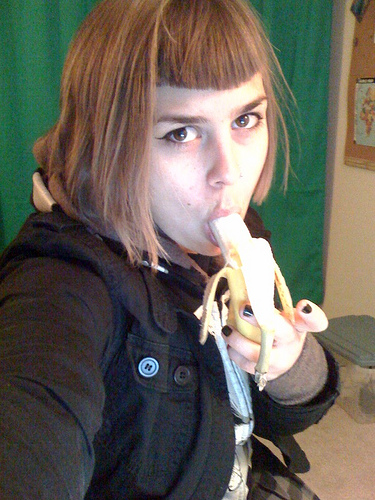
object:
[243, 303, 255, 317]
fingernails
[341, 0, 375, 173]
corkboard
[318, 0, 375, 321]
wall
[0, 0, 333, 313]
curtain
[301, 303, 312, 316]
nails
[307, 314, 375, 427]
plastic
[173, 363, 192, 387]
button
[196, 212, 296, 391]
banana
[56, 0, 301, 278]
girl hair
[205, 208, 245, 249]
mouth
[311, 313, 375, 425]
bin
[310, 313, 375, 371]
lid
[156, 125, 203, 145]
eye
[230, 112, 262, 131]
eye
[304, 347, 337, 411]
shadow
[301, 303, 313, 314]
nail polish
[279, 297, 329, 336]
pointer finger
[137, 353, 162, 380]
button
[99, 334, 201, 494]
pocket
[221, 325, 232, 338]
nail polish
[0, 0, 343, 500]
girl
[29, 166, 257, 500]
shirt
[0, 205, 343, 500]
coat